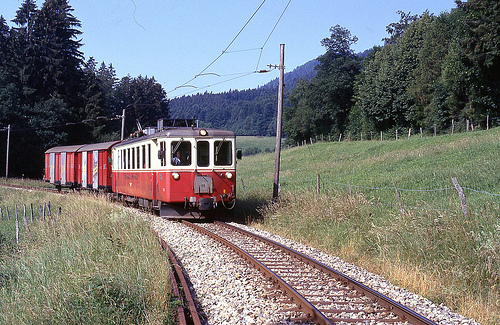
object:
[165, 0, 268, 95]
wires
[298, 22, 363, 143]
tree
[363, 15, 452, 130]
tree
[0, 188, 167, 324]
grass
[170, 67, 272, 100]
wires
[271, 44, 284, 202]
pole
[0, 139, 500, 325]
ground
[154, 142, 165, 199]
door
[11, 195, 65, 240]
stakes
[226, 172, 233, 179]
headlight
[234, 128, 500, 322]
grass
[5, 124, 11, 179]
pole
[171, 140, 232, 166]
three windshields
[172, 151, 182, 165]
conductor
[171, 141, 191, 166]
window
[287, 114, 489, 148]
fence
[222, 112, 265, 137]
trees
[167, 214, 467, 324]
path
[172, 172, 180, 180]
headlight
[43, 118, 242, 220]
train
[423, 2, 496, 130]
trees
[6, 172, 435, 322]
tracks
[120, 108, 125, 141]
pole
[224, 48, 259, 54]
wires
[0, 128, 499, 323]
floor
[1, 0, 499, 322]
forrest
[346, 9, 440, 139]
branches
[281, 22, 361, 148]
branches